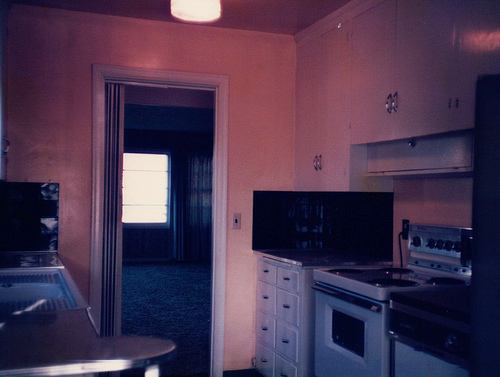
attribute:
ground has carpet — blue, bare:
[121, 264, 210, 376]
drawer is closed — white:
[275, 264, 303, 292]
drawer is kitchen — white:
[256, 258, 277, 284]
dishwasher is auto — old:
[389, 285, 473, 376]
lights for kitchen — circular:
[170, 0, 221, 23]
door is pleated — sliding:
[104, 84, 120, 336]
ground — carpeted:
[119, 243, 227, 374]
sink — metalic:
[14, 267, 75, 347]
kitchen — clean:
[4, 3, 495, 374]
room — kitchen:
[4, 5, 498, 375]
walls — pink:
[12, 11, 496, 346]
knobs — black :
[407, 228, 467, 263]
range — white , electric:
[305, 209, 482, 374]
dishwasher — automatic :
[375, 286, 476, 375]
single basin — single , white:
[0, 268, 91, 325]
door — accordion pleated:
[108, 79, 125, 349]